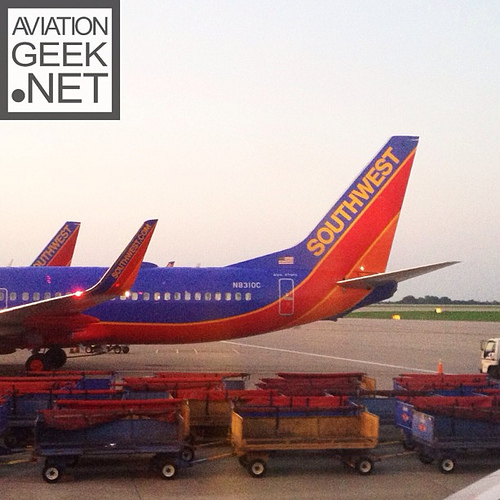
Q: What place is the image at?
A: It is at the runway.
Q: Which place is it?
A: It is a runway.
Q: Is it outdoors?
A: Yes, it is outdoors.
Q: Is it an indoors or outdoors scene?
A: It is outdoors.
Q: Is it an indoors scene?
A: No, it is outdoors.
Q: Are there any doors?
A: Yes, there is a door.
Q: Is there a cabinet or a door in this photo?
A: Yes, there is a door.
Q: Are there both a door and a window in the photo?
A: Yes, there are both a door and a window.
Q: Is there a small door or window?
A: Yes, there is a small door.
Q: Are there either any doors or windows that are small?
A: Yes, the door is small.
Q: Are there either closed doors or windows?
A: Yes, there is a closed door.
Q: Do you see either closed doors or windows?
A: Yes, there is a closed door.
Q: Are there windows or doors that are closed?
A: Yes, the door is closed.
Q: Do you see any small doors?
A: Yes, there is a small door.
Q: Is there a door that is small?
A: Yes, there is a door that is small.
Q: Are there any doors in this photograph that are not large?
A: Yes, there is a small door.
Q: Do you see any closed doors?
A: Yes, there is a closed door.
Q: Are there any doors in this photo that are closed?
A: Yes, there is a door that is closed.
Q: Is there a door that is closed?
A: Yes, there is a door that is closed.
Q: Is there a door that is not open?
A: Yes, there is an closed door.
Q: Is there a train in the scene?
A: No, there are no trains.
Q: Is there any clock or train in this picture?
A: No, there are no trains or clocks.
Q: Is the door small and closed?
A: Yes, the door is small and closed.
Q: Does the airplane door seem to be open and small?
A: No, the door is small but closed.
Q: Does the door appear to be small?
A: Yes, the door is small.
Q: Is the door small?
A: Yes, the door is small.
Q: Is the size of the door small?
A: Yes, the door is small.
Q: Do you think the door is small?
A: Yes, the door is small.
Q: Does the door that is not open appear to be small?
A: Yes, the door is small.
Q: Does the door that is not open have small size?
A: Yes, the door is small.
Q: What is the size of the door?
A: The door is small.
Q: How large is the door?
A: The door is small.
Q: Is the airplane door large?
A: No, the door is small.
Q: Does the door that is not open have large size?
A: No, the door is small.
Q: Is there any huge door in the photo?
A: No, there is a door but it is small.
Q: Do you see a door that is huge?
A: No, there is a door but it is small.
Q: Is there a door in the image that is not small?
A: No, there is a door but it is small.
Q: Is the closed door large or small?
A: The door is small.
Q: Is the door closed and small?
A: Yes, the door is closed and small.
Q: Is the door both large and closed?
A: No, the door is closed but small.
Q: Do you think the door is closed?
A: Yes, the door is closed.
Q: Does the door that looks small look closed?
A: Yes, the door is closed.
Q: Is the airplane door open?
A: No, the door is closed.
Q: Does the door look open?
A: No, the door is closed.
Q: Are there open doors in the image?
A: No, there is a door but it is closed.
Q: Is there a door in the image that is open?
A: No, there is a door but it is closed.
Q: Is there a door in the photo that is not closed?
A: No, there is a door but it is closed.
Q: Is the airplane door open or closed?
A: The door is closed.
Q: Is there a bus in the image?
A: No, there are no buses.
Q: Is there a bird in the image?
A: No, there are no birds.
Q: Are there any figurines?
A: No, there are no figurines.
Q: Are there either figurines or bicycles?
A: No, there are no figurines or bicycles.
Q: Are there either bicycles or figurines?
A: No, there are no figurines or bicycles.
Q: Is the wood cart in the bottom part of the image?
A: Yes, the cart is in the bottom of the image.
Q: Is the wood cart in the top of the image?
A: No, the cart is in the bottom of the image.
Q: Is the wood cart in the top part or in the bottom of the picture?
A: The cart is in the bottom of the image.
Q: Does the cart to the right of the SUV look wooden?
A: Yes, the cart is wooden.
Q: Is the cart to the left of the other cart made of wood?
A: Yes, the cart is made of wood.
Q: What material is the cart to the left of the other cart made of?
A: The cart is made of wood.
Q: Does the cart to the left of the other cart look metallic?
A: No, the cart is wooden.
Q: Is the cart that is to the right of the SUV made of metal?
A: No, the cart is made of wood.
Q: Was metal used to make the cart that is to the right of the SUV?
A: No, the cart is made of wood.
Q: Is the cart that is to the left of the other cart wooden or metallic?
A: The cart is wooden.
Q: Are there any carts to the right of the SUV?
A: Yes, there is a cart to the right of the SUV.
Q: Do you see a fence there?
A: No, there are no fences.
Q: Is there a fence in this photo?
A: No, there are no fences.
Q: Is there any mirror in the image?
A: No, there are no mirrors.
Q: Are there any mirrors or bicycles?
A: No, there are no mirrors or bicycles.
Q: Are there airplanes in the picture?
A: Yes, there is an airplane.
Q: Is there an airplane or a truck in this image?
A: Yes, there is an airplane.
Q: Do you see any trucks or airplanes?
A: Yes, there is an airplane.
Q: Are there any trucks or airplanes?
A: Yes, there is an airplane.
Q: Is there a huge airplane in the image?
A: Yes, there is a huge airplane.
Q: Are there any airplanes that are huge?
A: Yes, there is an airplane that is huge.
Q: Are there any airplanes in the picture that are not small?
A: Yes, there is a huge airplane.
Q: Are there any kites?
A: No, there are no kites.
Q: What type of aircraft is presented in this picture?
A: The aircraft is an airplane.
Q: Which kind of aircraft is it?
A: The aircraft is an airplane.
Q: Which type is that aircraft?
A: This is an airplane.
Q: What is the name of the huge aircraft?
A: The aircraft is an airplane.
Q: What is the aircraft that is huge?
A: The aircraft is an airplane.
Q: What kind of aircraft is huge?
A: The aircraft is an airplane.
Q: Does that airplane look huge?
A: Yes, the airplane is huge.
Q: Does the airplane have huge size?
A: Yes, the airplane is huge.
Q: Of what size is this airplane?
A: The airplane is huge.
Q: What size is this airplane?
A: The airplane is huge.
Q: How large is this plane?
A: The plane is huge.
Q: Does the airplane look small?
A: No, the airplane is huge.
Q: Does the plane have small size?
A: No, the plane is huge.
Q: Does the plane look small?
A: No, the plane is huge.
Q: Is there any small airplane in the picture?
A: No, there is an airplane but it is huge.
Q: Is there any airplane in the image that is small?
A: No, there is an airplane but it is huge.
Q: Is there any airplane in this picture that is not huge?
A: No, there is an airplane but it is huge.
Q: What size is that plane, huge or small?
A: The plane is huge.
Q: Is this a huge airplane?
A: Yes, this is a huge airplane.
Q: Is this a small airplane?
A: No, this is a huge airplane.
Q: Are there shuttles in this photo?
A: No, there are no shuttles.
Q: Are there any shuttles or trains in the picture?
A: No, there are no shuttles or trains.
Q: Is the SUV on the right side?
A: No, the SUV is on the left of the image.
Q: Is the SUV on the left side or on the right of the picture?
A: The SUV is on the left of the image.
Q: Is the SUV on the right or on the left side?
A: The SUV is on the left of the image.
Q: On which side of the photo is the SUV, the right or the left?
A: The SUV is on the left of the image.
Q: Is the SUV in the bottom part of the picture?
A: Yes, the SUV is in the bottom of the image.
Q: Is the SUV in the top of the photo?
A: No, the SUV is in the bottom of the image.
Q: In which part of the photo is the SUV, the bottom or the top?
A: The SUV is in the bottom of the image.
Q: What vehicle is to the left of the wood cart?
A: The vehicle is a SUV.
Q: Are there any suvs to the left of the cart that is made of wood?
A: Yes, there is a SUV to the left of the cart.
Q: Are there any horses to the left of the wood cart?
A: No, there is a SUV to the left of the cart.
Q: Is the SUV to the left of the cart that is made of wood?
A: Yes, the SUV is to the left of the cart.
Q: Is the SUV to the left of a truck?
A: No, the SUV is to the left of the cart.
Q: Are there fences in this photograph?
A: No, there are no fences.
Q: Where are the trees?
A: The trees are on the runway.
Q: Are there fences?
A: No, there are no fences.